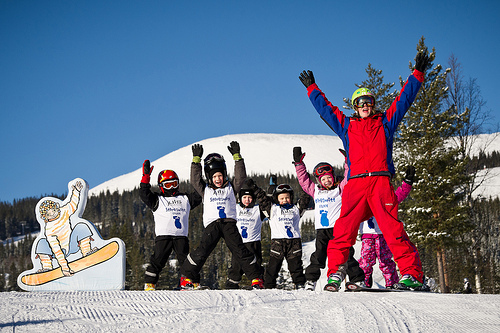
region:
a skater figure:
[19, 180, 124, 294]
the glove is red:
[141, 160, 152, 184]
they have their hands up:
[141, 53, 433, 182]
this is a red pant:
[326, 177, 421, 277]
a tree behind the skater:
[400, 73, 497, 272]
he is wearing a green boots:
[326, 270, 421, 290]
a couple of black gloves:
[298, 51, 430, 84]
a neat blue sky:
[20, 12, 253, 103]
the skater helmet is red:
[159, 170, 179, 182]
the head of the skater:
[354, 90, 375, 117]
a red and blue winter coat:
[305, 70, 423, 177]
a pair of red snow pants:
[325, 173, 422, 280]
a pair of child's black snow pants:
[142, 235, 193, 282]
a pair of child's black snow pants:
[185, 218, 246, 281]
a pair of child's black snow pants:
[232, 240, 262, 280]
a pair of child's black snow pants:
[262, 237, 305, 288]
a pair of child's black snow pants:
[305, 228, 367, 283]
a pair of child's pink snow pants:
[357, 235, 397, 286]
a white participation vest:
[152, 195, 189, 237]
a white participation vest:
[200, 185, 237, 225]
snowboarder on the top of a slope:
[285, 44, 440, 292]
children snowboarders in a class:
[121, 128, 421, 301]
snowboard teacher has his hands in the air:
[284, 41, 452, 292]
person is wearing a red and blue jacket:
[305, 68, 436, 176]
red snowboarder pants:
[320, 175, 427, 286]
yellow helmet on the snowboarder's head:
[350, 81, 374, 103]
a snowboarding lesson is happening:
[135, 51, 442, 297]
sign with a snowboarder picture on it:
[20, 171, 132, 291]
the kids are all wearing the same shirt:
[150, 182, 392, 248]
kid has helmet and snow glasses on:
[156, 167, 180, 194]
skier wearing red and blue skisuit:
[291, 34, 453, 299]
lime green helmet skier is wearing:
[350, 87, 374, 102]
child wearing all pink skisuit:
[340, 164, 422, 289]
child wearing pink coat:
[292, 142, 361, 288]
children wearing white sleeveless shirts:
[130, 133, 414, 295]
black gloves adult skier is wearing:
[297, 54, 433, 84]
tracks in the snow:
[4, 284, 499, 331]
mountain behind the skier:
[105, 97, 499, 169]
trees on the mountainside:
[5, 156, 490, 292]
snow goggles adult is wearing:
[353, 98, 374, 107]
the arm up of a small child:
[139, 159, 159, 206]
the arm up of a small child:
[186, 181, 202, 207]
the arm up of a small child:
[188, 141, 205, 198]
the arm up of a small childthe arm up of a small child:
[224, 140, 245, 192]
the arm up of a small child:
[242, 175, 273, 210]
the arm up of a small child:
[297, 190, 312, 214]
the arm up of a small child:
[292, 143, 314, 193]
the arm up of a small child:
[336, 148, 349, 190]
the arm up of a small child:
[392, 164, 415, 202]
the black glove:
[222, 140, 239, 156]